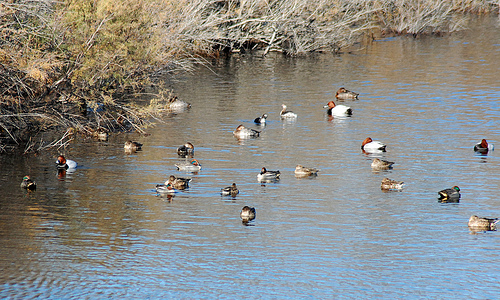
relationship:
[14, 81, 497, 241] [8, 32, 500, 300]
ducks in pond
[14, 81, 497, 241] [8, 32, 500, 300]
duck swimming in water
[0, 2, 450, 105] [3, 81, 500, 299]
brush along side of water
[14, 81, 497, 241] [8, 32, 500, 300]
ducks on pond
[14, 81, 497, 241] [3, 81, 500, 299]
ducks in water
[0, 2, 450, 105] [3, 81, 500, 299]
bush along side of water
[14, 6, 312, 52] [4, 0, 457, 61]
twig branch of bushes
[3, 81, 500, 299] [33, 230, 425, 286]
water has ripples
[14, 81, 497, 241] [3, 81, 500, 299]
ducks swimming in water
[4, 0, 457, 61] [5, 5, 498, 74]
trees lining bank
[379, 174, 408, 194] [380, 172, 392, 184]
duck with brown head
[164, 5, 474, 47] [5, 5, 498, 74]
branches on bank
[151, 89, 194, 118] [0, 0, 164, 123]
duck swimming by tree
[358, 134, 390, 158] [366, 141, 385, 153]
duck color white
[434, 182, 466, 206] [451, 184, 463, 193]
duck with green head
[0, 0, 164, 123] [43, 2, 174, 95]
leaves has green-yellow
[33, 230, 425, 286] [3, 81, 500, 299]
blue sky reflecting off water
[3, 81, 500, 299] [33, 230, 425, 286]
water reflecting blue sky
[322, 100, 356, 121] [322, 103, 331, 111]
duck has beak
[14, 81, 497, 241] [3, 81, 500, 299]
ducks are on water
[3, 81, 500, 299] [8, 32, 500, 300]
water body a part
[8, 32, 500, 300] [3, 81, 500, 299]
surface of water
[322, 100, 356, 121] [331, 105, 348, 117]
duck has white part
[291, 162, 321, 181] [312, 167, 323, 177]
duck has has tail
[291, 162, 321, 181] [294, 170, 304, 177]
duck has chest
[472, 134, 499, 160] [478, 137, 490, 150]
duck has red part